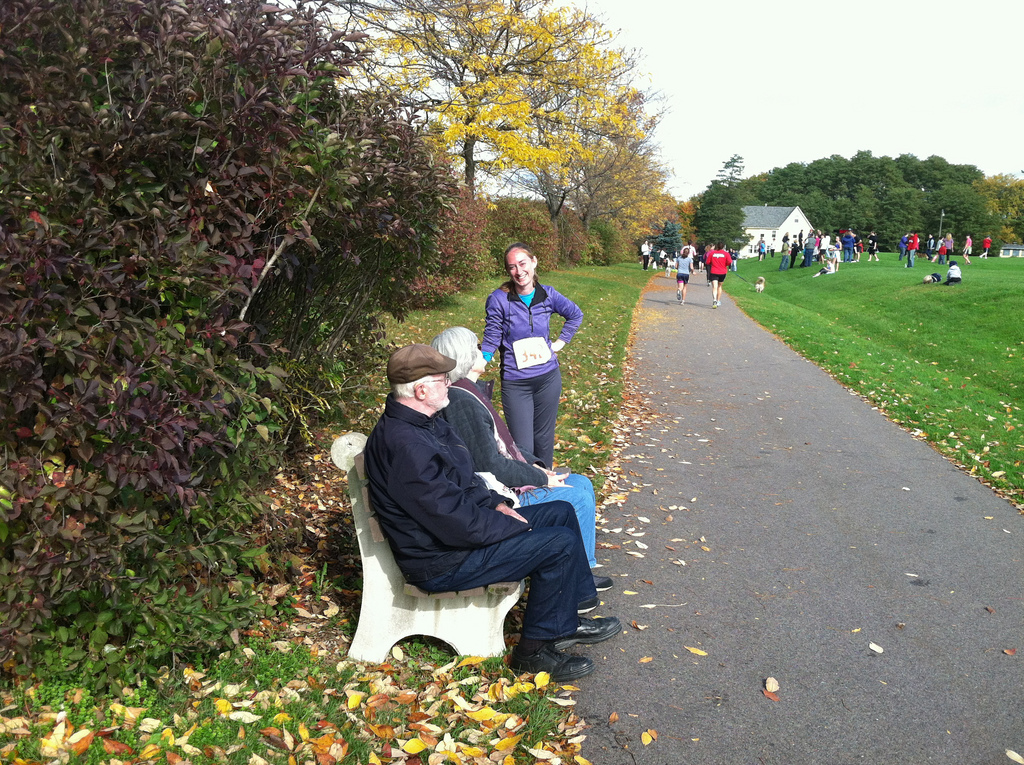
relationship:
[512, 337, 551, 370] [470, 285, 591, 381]
paper on jacket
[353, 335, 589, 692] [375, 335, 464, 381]
man wears hat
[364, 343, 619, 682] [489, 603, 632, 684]
man has boots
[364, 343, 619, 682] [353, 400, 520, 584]
man wears jacket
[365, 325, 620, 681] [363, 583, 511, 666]
couple people on a bench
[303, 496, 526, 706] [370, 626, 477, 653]
bench painted white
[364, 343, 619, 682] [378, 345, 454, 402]
man wearing a hat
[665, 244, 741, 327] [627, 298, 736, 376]
two people running on cement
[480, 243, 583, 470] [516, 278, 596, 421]
woman wearing purple jacket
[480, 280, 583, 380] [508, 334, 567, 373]
jacket has a sign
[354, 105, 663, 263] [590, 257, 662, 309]
tree has yellow leaves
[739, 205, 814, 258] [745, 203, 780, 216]
building has gray roof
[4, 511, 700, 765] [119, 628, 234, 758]
fallen leaves on grass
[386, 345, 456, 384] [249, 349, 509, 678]
hat on top of mans head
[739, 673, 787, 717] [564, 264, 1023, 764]
leaves on top of concrete path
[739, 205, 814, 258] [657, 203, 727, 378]
building in back of trees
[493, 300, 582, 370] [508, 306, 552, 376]
jacket with blue shirt underneath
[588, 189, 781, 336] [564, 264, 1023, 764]
group of people running around concrete path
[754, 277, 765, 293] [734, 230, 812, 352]
dog running in grass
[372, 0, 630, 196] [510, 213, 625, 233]
tree with thin light green flowers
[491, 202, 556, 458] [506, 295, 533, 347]
woman in purple jacket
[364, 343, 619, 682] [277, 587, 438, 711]
man in blue jacket sitting on bench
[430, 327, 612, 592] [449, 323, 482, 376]
lady with grey hair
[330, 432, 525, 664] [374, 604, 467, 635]
bench park bench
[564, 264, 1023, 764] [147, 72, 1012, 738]
concrete path in a park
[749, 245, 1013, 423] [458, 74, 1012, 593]
grass in a park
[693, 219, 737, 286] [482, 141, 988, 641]
man walking in park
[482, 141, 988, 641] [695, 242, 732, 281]
park with shirt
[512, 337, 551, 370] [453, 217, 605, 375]
paper on a woman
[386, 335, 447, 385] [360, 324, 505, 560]
hat on a man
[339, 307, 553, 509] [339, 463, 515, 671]
couple sitting on a bench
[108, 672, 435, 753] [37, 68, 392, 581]
leaves falling from bush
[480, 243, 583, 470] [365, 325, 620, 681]
woman talking to couple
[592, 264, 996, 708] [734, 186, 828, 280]
concrete path leading to a building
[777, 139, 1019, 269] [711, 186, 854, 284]
evergreens behind building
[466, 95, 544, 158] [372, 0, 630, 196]
autumn leaves on tree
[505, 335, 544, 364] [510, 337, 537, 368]
paper with number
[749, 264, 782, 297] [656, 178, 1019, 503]
dog in fields